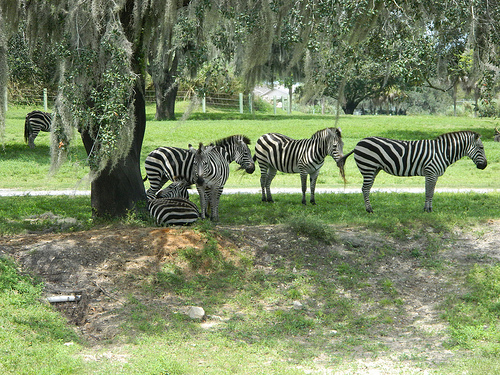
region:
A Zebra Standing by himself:
[343, 120, 493, 227]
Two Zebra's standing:
[252, 124, 489, 220]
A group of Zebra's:
[142, 114, 492, 239]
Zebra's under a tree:
[97, 26, 499, 231]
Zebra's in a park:
[12, 93, 499, 232]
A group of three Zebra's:
[138, 130, 258, 243]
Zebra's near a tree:
[68, 90, 260, 250]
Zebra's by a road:
[141, 111, 493, 235]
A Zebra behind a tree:
[9, 79, 154, 184]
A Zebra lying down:
[141, 170, 210, 245]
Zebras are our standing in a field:
[105, 77, 496, 345]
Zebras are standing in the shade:
[110, 87, 497, 348]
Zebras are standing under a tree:
[110, 6, 495, 347]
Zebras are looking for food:
[86, 37, 496, 368]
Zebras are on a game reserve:
[91, 63, 496, 373]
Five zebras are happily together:
[87, 52, 495, 369]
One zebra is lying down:
[113, 51, 493, 351]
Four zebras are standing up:
[135, 110, 493, 263]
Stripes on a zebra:
[362, 140, 437, 170]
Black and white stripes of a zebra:
[376, 140, 434, 171]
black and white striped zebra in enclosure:
[0, 176, 85, 233]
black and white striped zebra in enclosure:
[155, 170, 189, 222]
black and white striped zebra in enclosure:
[188, 126, 245, 226]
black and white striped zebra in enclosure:
[143, 131, 248, 206]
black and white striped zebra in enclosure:
[261, 121, 353, 232]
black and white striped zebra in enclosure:
[346, 116, 497, 214]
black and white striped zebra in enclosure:
[18, 108, 98, 169]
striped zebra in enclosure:
[251, 128, 349, 188]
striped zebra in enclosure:
[348, 120, 478, 192]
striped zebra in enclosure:
[133, 128, 260, 245]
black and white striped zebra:
[19, 107, 51, 145]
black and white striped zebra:
[42, 92, 70, 144]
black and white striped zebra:
[148, 172, 182, 224]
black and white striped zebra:
[169, 117, 244, 205]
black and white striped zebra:
[266, 122, 334, 202]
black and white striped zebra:
[359, 122, 480, 206]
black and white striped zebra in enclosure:
[281, 116, 339, 198]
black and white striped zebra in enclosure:
[135, 180, 216, 241]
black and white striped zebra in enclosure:
[31, 108, 57, 140]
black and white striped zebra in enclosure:
[48, 99, 70, 155]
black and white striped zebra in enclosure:
[191, 150, 224, 214]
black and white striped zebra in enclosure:
[151, 135, 256, 171]